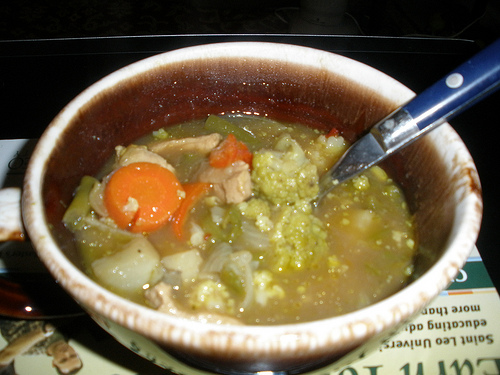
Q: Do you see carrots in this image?
A: Yes, there is a carrot.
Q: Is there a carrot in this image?
A: Yes, there is a carrot.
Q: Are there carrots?
A: Yes, there is a carrot.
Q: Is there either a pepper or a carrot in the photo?
A: Yes, there is a carrot.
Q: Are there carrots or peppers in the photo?
A: Yes, there is a carrot.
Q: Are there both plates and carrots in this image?
A: No, there is a carrot but no plates.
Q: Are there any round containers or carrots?
A: Yes, there is a round carrot.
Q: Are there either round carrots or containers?
A: Yes, there is a round carrot.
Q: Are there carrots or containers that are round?
A: Yes, the carrot is round.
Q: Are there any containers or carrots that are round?
A: Yes, the carrot is round.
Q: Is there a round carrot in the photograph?
A: Yes, there is a round carrot.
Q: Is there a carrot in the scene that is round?
A: Yes, there is a carrot that is round.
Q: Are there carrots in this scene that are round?
A: Yes, there is a carrot that is round.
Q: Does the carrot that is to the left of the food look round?
A: Yes, the carrot is round.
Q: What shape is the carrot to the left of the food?
A: The carrot is round.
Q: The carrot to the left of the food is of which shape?
A: The carrot is round.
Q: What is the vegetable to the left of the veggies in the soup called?
A: The vegetable is a carrot.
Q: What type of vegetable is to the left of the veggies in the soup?
A: The vegetable is a carrot.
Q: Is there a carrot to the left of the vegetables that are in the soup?
A: Yes, there is a carrot to the left of the vegetables.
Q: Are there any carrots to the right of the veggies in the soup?
A: No, the carrot is to the left of the vegetables.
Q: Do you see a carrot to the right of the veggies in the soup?
A: No, the carrot is to the left of the vegetables.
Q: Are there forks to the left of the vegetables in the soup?
A: No, there is a carrot to the left of the vegetables.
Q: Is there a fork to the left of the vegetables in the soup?
A: No, there is a carrot to the left of the vegetables.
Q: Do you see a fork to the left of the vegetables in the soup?
A: No, there is a carrot to the left of the vegetables.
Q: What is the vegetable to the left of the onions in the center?
A: The vegetable is a carrot.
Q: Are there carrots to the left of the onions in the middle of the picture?
A: Yes, there is a carrot to the left of the onions.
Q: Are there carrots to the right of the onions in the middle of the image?
A: No, the carrot is to the left of the onions.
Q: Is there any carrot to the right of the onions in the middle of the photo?
A: No, the carrot is to the left of the onions.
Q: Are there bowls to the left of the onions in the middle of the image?
A: No, there is a carrot to the left of the onions.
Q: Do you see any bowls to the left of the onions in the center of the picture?
A: No, there is a carrot to the left of the onions.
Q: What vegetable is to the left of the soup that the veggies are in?
A: The vegetable is a carrot.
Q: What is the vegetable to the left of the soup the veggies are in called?
A: The vegetable is a carrot.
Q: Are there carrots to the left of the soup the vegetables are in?
A: Yes, there is a carrot to the left of the soup.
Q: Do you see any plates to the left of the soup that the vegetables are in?
A: No, there is a carrot to the left of the soup.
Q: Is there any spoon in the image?
A: Yes, there is a spoon.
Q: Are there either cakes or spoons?
A: Yes, there is a spoon.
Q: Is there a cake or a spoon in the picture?
A: Yes, there is a spoon.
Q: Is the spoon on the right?
A: Yes, the spoon is on the right of the image.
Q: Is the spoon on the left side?
A: No, the spoon is on the right of the image.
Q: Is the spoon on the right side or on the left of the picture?
A: The spoon is on the right of the image.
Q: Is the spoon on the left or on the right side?
A: The spoon is on the right of the image.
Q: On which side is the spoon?
A: The spoon is on the right of the image.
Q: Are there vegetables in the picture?
A: Yes, there are vegetables.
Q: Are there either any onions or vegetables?
A: Yes, there are vegetables.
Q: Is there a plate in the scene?
A: No, there are no plates.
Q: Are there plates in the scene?
A: No, there are no plates.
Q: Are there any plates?
A: No, there are no plates.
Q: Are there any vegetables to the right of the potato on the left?
A: Yes, there are vegetables to the right of the potato.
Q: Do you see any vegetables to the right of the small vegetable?
A: Yes, there are vegetables to the right of the potato.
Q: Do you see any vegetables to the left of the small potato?
A: No, the vegetables are to the right of the potato.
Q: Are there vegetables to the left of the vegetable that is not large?
A: No, the vegetables are to the right of the potato.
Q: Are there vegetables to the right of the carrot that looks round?
A: Yes, there are vegetables to the right of the carrot.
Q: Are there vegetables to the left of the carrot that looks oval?
A: No, the vegetables are to the right of the carrot.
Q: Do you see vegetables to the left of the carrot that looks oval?
A: No, the vegetables are to the right of the carrot.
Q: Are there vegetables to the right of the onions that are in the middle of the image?
A: Yes, there are vegetables to the right of the onions.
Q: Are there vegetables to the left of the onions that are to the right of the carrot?
A: No, the vegetables are to the right of the onions.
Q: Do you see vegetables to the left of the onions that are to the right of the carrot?
A: No, the vegetables are to the right of the onions.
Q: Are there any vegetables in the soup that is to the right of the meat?
A: Yes, there are vegetables in the soup.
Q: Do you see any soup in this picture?
A: Yes, there is soup.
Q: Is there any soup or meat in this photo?
A: Yes, there is soup.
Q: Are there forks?
A: No, there are no forks.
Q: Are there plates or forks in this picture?
A: No, there are no forks or plates.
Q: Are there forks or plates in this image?
A: No, there are no forks or plates.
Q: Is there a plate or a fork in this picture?
A: No, there are no forks or plates.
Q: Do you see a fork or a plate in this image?
A: No, there are no forks or plates.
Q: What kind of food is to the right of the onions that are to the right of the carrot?
A: The food is soup.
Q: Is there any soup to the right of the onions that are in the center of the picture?
A: Yes, there is soup to the right of the onions.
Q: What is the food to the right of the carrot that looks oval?
A: The food is soup.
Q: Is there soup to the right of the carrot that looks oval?
A: Yes, there is soup to the right of the carrot.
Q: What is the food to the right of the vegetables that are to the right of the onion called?
A: The food is soup.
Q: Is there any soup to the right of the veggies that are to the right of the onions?
A: Yes, there is soup to the right of the vegetables.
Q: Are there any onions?
A: Yes, there are onions.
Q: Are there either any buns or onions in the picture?
A: Yes, there are onions.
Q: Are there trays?
A: No, there are no trays.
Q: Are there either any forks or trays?
A: No, there are no trays or forks.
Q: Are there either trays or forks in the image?
A: No, there are no trays or forks.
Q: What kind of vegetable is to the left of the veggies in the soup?
A: The vegetables are onions.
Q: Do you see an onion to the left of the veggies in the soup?
A: Yes, there are onions to the left of the vegetables.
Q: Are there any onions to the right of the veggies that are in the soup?
A: No, the onions are to the left of the veggies.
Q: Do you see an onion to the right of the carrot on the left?
A: Yes, there are onions to the right of the carrot.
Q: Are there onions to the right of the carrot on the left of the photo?
A: Yes, there are onions to the right of the carrot.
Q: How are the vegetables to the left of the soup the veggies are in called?
A: The vegetables are onions.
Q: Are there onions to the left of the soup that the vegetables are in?
A: Yes, there are onions to the left of the soup.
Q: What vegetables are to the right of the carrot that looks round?
A: The vegetables are onions.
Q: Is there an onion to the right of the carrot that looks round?
A: Yes, there are onions to the right of the carrot.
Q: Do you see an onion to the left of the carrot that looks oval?
A: No, the onions are to the right of the carrot.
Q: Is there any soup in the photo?
A: Yes, there is soup.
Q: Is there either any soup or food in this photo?
A: Yes, there is soup.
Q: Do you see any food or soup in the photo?
A: Yes, there is soup.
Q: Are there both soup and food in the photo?
A: Yes, there are both soup and food.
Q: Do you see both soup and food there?
A: Yes, there are both soup and food.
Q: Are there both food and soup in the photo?
A: Yes, there are both soup and food.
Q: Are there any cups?
A: No, there are no cups.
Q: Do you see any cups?
A: No, there are no cups.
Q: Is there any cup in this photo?
A: No, there are no cups.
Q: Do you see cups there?
A: No, there are no cups.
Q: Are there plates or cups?
A: No, there are no cups or plates.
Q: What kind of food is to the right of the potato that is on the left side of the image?
A: The food is soup.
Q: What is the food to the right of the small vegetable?
A: The food is soup.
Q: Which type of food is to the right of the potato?
A: The food is soup.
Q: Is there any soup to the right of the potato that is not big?
A: Yes, there is soup to the right of the potato.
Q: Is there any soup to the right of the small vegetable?
A: Yes, there is soup to the right of the potato.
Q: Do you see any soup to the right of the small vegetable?
A: Yes, there is soup to the right of the potato.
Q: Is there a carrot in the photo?
A: Yes, there is a carrot.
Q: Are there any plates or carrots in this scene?
A: Yes, there is a carrot.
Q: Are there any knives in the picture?
A: No, there are no knives.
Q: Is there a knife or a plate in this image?
A: No, there are no knives or plates.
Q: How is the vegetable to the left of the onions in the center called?
A: The vegetable is a carrot.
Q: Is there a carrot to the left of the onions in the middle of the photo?
A: Yes, there is a carrot to the left of the onions.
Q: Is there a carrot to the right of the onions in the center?
A: No, the carrot is to the left of the onions.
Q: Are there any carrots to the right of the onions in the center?
A: No, the carrot is to the left of the onions.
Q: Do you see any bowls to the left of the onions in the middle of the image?
A: No, there is a carrot to the left of the onions.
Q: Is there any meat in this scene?
A: Yes, there is meat.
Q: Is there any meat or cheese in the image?
A: Yes, there is meat.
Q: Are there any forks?
A: No, there are no forks.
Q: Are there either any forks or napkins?
A: No, there are no forks or napkins.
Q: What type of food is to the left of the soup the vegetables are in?
A: The food is meat.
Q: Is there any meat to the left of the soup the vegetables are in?
A: Yes, there is meat to the left of the soup.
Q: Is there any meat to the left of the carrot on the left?
A: No, the meat is to the right of the carrot.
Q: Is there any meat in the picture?
A: Yes, there is meat.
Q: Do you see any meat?
A: Yes, there is meat.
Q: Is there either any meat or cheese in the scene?
A: Yes, there is meat.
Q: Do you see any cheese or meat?
A: Yes, there is meat.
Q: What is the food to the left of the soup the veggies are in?
A: The food is meat.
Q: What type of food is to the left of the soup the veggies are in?
A: The food is meat.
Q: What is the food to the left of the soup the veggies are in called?
A: The food is meat.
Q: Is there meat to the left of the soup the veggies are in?
A: Yes, there is meat to the left of the soup.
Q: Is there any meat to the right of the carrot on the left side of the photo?
A: Yes, there is meat to the right of the carrot.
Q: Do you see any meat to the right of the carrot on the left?
A: Yes, there is meat to the right of the carrot.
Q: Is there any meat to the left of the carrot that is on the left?
A: No, the meat is to the right of the carrot.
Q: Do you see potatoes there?
A: Yes, there is a potato.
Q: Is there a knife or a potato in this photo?
A: Yes, there is a potato.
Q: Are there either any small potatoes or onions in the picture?
A: Yes, there is a small potato.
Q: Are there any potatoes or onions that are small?
A: Yes, the potato is small.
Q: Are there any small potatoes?
A: Yes, there is a small potato.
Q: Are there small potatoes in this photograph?
A: Yes, there is a small potato.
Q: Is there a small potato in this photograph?
A: Yes, there is a small potato.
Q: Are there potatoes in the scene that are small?
A: Yes, there is a potato that is small.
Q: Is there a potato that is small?
A: Yes, there is a potato that is small.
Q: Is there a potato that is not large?
A: Yes, there is a small potato.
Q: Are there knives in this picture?
A: No, there are no knives.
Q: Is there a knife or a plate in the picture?
A: No, there are no knives or plates.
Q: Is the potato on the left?
A: Yes, the potato is on the left of the image.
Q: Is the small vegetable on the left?
A: Yes, the potato is on the left of the image.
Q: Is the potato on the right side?
A: No, the potato is on the left of the image.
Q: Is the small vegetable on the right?
A: No, the potato is on the left of the image.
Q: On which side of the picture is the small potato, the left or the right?
A: The potato is on the left of the image.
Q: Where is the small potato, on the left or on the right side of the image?
A: The potato is on the left of the image.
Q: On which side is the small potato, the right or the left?
A: The potato is on the left of the image.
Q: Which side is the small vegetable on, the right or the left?
A: The potato is on the left of the image.